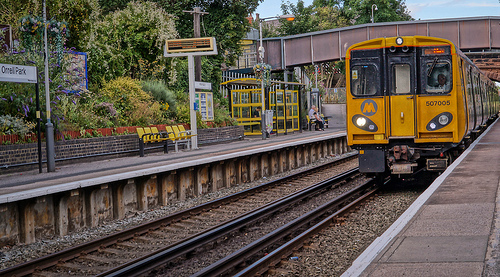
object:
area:
[221, 78, 307, 136]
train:
[343, 33, 500, 185]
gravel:
[0, 192, 421, 277]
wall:
[1, 135, 138, 172]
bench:
[135, 124, 198, 156]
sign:
[165, 37, 214, 53]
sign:
[195, 82, 214, 122]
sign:
[59, 52, 90, 97]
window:
[426, 61, 451, 92]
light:
[430, 115, 449, 130]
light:
[395, 37, 403, 45]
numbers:
[426, 100, 451, 107]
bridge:
[263, 15, 499, 70]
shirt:
[309, 109, 319, 119]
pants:
[315, 120, 324, 129]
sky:
[389, 0, 495, 25]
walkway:
[256, 16, 499, 72]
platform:
[348, 120, 500, 276]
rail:
[92, 188, 378, 277]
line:
[335, 183, 437, 277]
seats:
[143, 134, 197, 144]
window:
[394, 64, 411, 94]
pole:
[35, 81, 43, 173]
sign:
[0, 63, 37, 83]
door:
[387, 53, 417, 136]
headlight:
[356, 116, 367, 126]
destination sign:
[424, 47, 446, 54]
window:
[351, 64, 377, 96]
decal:
[360, 99, 378, 117]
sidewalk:
[0, 126, 346, 195]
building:
[219, 78, 308, 136]